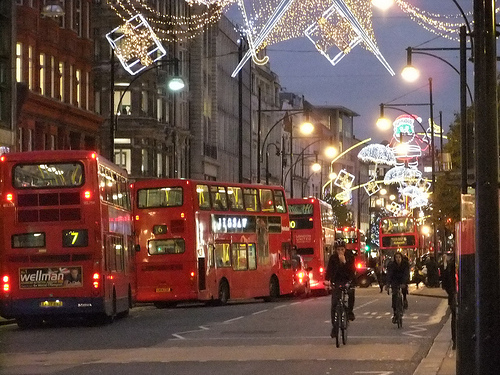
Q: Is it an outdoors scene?
A: Yes, it is outdoors.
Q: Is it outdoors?
A: Yes, it is outdoors.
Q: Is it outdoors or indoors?
A: It is outdoors.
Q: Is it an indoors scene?
A: No, it is outdoors.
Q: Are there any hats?
A: Yes, there is a hat.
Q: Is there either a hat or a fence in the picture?
A: Yes, there is a hat.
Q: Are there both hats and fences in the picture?
A: No, there is a hat but no fences.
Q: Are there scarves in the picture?
A: No, there are no scarves.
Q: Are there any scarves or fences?
A: No, there are no scarves or fences.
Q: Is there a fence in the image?
A: No, there are no fences.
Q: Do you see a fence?
A: No, there are no fences.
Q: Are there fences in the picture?
A: No, there are no fences.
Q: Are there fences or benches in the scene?
A: No, there are no fences or benches.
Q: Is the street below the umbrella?
A: Yes, the street is below the umbrella.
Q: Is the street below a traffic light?
A: No, the street is below the umbrella.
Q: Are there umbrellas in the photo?
A: Yes, there is an umbrella.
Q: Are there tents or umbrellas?
A: Yes, there is an umbrella.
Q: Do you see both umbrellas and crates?
A: No, there is an umbrella but no crates.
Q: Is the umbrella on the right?
A: Yes, the umbrella is on the right of the image.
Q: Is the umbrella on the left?
A: No, the umbrella is on the right of the image.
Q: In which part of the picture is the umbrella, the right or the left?
A: The umbrella is on the right of the image.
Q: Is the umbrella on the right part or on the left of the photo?
A: The umbrella is on the right of the image.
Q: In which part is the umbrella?
A: The umbrella is on the right of the image.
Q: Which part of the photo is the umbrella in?
A: The umbrella is on the right of the image.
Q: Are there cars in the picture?
A: No, there are no cars.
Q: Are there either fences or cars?
A: No, there are no cars or fences.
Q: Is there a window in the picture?
A: Yes, there is a window.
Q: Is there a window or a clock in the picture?
A: Yes, there is a window.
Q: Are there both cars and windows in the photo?
A: No, there is a window but no cars.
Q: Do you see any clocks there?
A: No, there are no clocks.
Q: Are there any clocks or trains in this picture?
A: No, there are no clocks or trains.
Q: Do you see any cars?
A: No, there are no cars.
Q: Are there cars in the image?
A: No, there are no cars.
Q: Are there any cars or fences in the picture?
A: No, there are no cars or fences.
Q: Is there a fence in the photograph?
A: No, there are no fences.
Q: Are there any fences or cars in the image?
A: No, there are no fences or cars.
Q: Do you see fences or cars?
A: No, there are no fences or cars.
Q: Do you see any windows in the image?
A: Yes, there is a window.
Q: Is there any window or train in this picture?
A: Yes, there is a window.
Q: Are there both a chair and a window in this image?
A: No, there is a window but no chairs.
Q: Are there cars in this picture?
A: No, there are no cars.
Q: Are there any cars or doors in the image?
A: No, there are no cars or doors.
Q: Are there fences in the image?
A: No, there are no fences.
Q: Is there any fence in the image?
A: No, there are no fences.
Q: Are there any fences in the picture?
A: No, there are no fences.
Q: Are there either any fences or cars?
A: No, there are no fences or cars.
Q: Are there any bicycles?
A: Yes, there is a bicycle.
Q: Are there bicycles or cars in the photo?
A: Yes, there is a bicycle.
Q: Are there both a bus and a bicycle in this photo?
A: Yes, there are both a bicycle and a bus.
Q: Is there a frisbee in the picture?
A: No, there are no frisbees.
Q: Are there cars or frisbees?
A: No, there are no frisbees or cars.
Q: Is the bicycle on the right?
A: Yes, the bicycle is on the right of the image.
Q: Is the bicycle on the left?
A: No, the bicycle is on the right of the image.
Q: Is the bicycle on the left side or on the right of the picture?
A: The bicycle is on the right of the image.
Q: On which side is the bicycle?
A: The bicycle is on the right of the image.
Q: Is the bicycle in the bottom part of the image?
A: Yes, the bicycle is in the bottom of the image.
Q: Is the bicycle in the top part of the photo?
A: No, the bicycle is in the bottom of the image.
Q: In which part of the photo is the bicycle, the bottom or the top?
A: The bicycle is in the bottom of the image.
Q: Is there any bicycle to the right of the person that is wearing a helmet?
A: Yes, there is a bicycle to the right of the person.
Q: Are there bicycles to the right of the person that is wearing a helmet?
A: Yes, there is a bicycle to the right of the person.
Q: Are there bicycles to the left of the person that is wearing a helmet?
A: No, the bicycle is to the right of the person.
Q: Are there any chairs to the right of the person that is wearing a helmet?
A: No, there is a bicycle to the right of the person.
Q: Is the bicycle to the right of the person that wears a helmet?
A: Yes, the bicycle is to the right of the person.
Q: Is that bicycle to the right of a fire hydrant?
A: No, the bicycle is to the right of the person.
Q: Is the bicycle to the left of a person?
A: No, the bicycle is to the right of a person.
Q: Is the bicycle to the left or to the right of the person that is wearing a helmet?
A: The bicycle is to the right of the person.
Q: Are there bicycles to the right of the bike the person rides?
A: Yes, there is a bicycle to the right of the bike.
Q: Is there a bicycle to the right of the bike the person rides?
A: Yes, there is a bicycle to the right of the bike.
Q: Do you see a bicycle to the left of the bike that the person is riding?
A: No, the bicycle is to the right of the bike.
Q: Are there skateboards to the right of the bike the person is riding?
A: No, there is a bicycle to the right of the bike.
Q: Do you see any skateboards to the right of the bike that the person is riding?
A: No, there is a bicycle to the right of the bike.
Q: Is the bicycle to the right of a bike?
A: Yes, the bicycle is to the right of a bike.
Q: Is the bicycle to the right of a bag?
A: No, the bicycle is to the right of a bike.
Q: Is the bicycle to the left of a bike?
A: No, the bicycle is to the right of a bike.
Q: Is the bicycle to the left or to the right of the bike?
A: The bicycle is to the right of the bike.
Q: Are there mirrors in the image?
A: No, there are no mirrors.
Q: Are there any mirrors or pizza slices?
A: No, there are no mirrors or pizza slices.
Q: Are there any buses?
A: Yes, there is a bus.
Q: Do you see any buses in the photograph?
A: Yes, there is a bus.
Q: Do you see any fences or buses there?
A: Yes, there is a bus.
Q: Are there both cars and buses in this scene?
A: No, there is a bus but no cars.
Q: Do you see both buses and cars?
A: No, there is a bus but no cars.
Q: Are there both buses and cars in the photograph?
A: No, there is a bus but no cars.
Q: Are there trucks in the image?
A: No, there are no trucks.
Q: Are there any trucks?
A: No, there are no trucks.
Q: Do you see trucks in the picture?
A: No, there are no trucks.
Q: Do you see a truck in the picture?
A: No, there are no trucks.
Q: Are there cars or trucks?
A: No, there are no trucks or cars.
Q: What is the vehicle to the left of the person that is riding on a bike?
A: The vehicle is a bus.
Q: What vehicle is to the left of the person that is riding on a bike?
A: The vehicle is a bus.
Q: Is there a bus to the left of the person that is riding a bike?
A: Yes, there is a bus to the left of the person.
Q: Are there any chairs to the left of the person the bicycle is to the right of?
A: No, there is a bus to the left of the person.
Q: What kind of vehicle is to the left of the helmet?
A: The vehicle is a bus.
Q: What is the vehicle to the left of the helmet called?
A: The vehicle is a bus.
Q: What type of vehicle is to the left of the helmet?
A: The vehicle is a bus.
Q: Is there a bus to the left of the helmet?
A: Yes, there is a bus to the left of the helmet.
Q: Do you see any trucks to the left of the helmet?
A: No, there is a bus to the left of the helmet.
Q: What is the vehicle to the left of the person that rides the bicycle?
A: The vehicle is a bus.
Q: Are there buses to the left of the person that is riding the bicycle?
A: Yes, there is a bus to the left of the person.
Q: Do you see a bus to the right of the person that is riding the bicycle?
A: No, the bus is to the left of the person.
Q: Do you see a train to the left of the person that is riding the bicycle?
A: No, there is a bus to the left of the person.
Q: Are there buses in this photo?
A: Yes, there is a bus.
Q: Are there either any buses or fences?
A: Yes, there is a bus.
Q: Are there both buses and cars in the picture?
A: No, there is a bus but no cars.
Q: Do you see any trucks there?
A: No, there are no trucks.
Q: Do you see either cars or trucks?
A: No, there are no trucks or cars.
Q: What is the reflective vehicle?
A: The vehicle is a bus.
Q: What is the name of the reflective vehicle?
A: The vehicle is a bus.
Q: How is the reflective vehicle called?
A: The vehicle is a bus.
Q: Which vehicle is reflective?
A: The vehicle is a bus.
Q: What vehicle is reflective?
A: The vehicle is a bus.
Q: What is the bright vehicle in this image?
A: The vehicle is a bus.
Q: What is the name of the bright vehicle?
A: The vehicle is a bus.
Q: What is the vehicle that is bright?
A: The vehicle is a bus.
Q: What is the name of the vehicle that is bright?
A: The vehicle is a bus.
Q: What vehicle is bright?
A: The vehicle is a bus.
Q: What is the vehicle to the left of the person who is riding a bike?
A: The vehicle is a bus.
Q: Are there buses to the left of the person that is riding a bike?
A: Yes, there is a bus to the left of the person.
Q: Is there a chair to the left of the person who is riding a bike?
A: No, there is a bus to the left of the person.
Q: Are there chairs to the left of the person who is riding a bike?
A: No, there is a bus to the left of the person.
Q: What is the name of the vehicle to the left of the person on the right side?
A: The vehicle is a bus.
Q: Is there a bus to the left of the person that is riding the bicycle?
A: Yes, there is a bus to the left of the person.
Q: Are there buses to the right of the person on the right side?
A: No, the bus is to the left of the person.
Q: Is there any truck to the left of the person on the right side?
A: No, there is a bus to the left of the person.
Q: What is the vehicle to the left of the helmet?
A: The vehicle is a bus.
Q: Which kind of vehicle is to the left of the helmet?
A: The vehicle is a bus.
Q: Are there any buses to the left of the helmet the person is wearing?
A: Yes, there is a bus to the left of the helmet.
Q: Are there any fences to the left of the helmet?
A: No, there is a bus to the left of the helmet.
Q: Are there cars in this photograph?
A: No, there are no cars.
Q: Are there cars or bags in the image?
A: No, there are no cars or bags.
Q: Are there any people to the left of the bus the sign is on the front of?
A: Yes, there is a person to the left of the bus.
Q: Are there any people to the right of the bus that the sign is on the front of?
A: No, the person is to the left of the bus.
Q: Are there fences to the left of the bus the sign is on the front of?
A: No, there is a person to the left of the bus.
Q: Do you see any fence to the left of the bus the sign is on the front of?
A: No, there is a person to the left of the bus.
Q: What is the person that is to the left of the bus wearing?
A: The person is wearing a helmet.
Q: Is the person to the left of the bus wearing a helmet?
A: Yes, the person is wearing a helmet.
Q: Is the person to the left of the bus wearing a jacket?
A: No, the person is wearing a helmet.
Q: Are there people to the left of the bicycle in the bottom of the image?
A: Yes, there is a person to the left of the bicycle.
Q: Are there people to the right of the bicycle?
A: No, the person is to the left of the bicycle.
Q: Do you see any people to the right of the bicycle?
A: No, the person is to the left of the bicycle.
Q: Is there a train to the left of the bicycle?
A: No, there is a person to the left of the bicycle.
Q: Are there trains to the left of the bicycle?
A: No, there is a person to the left of the bicycle.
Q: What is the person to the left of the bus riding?
A: The person is riding a bike.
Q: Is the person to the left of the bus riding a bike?
A: Yes, the person is riding a bike.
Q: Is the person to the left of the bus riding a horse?
A: No, the person is riding a bike.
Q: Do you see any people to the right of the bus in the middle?
A: Yes, there is a person to the right of the bus.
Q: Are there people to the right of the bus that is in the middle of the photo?
A: Yes, there is a person to the right of the bus.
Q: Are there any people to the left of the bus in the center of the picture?
A: No, the person is to the right of the bus.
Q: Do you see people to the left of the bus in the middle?
A: No, the person is to the right of the bus.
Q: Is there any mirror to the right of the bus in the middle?
A: No, there is a person to the right of the bus.